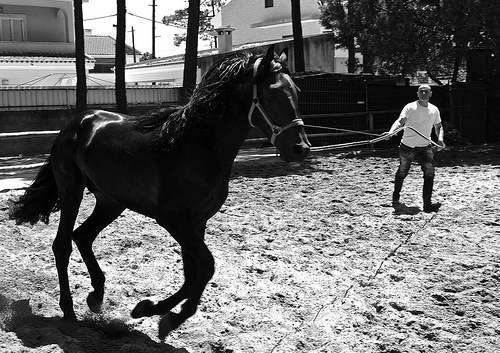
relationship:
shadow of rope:
[324, 188, 455, 334] [300, 108, 415, 166]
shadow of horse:
[19, 278, 132, 341] [37, 39, 321, 330]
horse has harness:
[37, 39, 321, 330] [253, 60, 305, 159]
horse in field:
[37, 39, 321, 330] [20, 88, 330, 323]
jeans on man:
[389, 132, 450, 243] [389, 70, 467, 207]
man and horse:
[389, 70, 467, 207] [37, 39, 321, 330]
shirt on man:
[395, 95, 456, 154] [389, 70, 467, 207]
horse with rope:
[37, 39, 321, 330] [300, 108, 415, 166]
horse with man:
[37, 39, 321, 330] [389, 70, 467, 207]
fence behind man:
[335, 76, 498, 133] [389, 70, 467, 207]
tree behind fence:
[364, 13, 476, 63] [335, 76, 498, 133]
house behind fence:
[219, 3, 333, 96] [335, 76, 498, 133]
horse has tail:
[37, 39, 321, 330] [0, 124, 106, 228]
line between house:
[144, 3, 198, 42] [219, 3, 333, 96]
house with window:
[219, 3, 333, 96] [14, 14, 32, 56]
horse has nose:
[37, 39, 321, 330] [282, 126, 316, 177]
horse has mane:
[37, 39, 321, 330] [164, 57, 233, 133]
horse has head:
[37, 39, 321, 330] [226, 46, 333, 182]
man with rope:
[389, 70, 467, 207] [300, 108, 415, 166]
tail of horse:
[0, 124, 106, 228] [37, 39, 321, 330]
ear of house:
[256, 37, 282, 85] [219, 3, 333, 96]